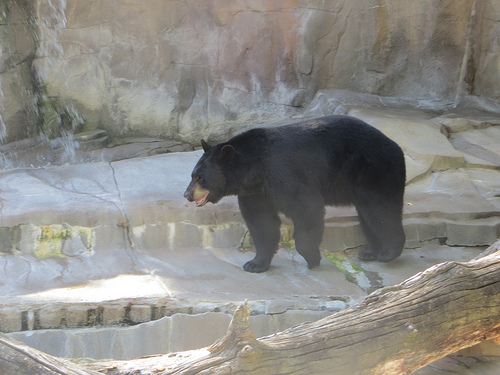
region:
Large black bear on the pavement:
[170, 119, 425, 292]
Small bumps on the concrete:
[8, 285, 53, 319]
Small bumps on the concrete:
[70, 280, 113, 315]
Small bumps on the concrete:
[218, 266, 294, 338]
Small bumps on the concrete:
[325, 232, 367, 292]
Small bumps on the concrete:
[428, 141, 470, 196]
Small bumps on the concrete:
[99, 119, 158, 186]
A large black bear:
[156, 95, 413, 286]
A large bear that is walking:
[173, 100, 415, 275]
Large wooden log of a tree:
[198, 263, 483, 365]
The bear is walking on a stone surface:
[108, 74, 415, 275]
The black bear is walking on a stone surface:
[106, 66, 413, 275]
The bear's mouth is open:
[180, 134, 265, 234]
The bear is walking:
[116, 96, 408, 281]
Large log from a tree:
[152, 265, 485, 365]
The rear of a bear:
[313, 103, 427, 273]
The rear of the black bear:
[311, 90, 447, 276]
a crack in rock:
[114, 215, 141, 257]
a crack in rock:
[97, 149, 127, 191]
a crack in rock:
[22, 55, 63, 121]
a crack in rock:
[433, 109, 483, 147]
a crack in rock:
[423, 227, 475, 261]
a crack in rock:
[288, 284, 363, 320]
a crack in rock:
[246, 291, 296, 331]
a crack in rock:
[12, 46, 78, 116]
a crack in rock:
[156, 26, 241, 106]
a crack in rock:
[296, 37, 334, 101]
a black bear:
[175, 106, 411, 276]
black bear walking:
[178, 110, 413, 276]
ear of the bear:
[196, 134, 213, 154]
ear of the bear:
[216, 140, 238, 162]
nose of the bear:
[181, 188, 193, 200]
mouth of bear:
[188, 195, 210, 208]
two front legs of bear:
[233, 195, 336, 282]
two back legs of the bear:
[349, 200, 410, 268]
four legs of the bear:
[233, 195, 411, 276]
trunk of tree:
[1, 238, 498, 374]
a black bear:
[178, 114, 433, 279]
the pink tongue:
[190, 192, 209, 207]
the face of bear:
[179, 161, 216, 208]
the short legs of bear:
[237, 197, 417, 277]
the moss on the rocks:
[11, 78, 364, 324]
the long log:
[180, 249, 497, 373]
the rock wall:
[5, 1, 497, 223]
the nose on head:
[182, 184, 197, 199]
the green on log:
[395, 287, 499, 358]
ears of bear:
[198, 137, 228, 162]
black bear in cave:
[183, 115, 406, 270]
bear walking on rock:
[183, 113, 407, 271]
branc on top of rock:
[90, 240, 497, 373]